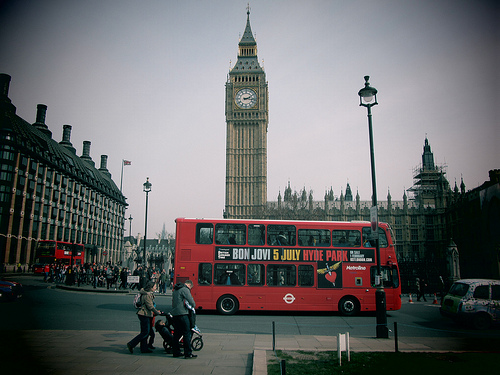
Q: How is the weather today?
A: It is partly cloudy.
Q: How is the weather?
A: It is partly cloudy.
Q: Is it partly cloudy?
A: Yes, it is partly cloudy.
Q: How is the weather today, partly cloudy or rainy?
A: It is partly cloudy.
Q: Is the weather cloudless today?
A: No, it is partly cloudy.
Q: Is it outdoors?
A: Yes, it is outdoors.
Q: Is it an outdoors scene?
A: Yes, it is outdoors.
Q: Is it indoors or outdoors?
A: It is outdoors.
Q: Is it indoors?
A: No, it is outdoors.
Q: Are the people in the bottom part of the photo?
A: Yes, the people are in the bottom of the image.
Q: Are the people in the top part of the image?
A: No, the people are in the bottom of the image.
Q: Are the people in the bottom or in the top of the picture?
A: The people are in the bottom of the image.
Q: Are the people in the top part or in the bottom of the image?
A: The people are in the bottom of the image.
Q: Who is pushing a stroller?
A: The people are pushing a stroller.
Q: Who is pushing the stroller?
A: The people are pushing a stroller.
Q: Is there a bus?
A: Yes, there is a bus.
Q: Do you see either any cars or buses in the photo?
A: Yes, there is a bus.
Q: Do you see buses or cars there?
A: Yes, there is a bus.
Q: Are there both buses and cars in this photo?
A: Yes, there are both a bus and a car.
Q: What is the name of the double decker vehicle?
A: The vehicle is a bus.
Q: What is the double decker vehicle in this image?
A: The vehicle is a bus.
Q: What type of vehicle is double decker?
A: The vehicle is a bus.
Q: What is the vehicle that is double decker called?
A: The vehicle is a bus.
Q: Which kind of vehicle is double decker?
A: The vehicle is a bus.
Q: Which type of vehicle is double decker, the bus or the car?
A: The bus is double decker.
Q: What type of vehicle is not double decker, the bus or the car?
A: The car is not double decker.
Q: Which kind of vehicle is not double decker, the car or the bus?
A: The car is not double decker.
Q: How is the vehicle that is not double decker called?
A: The vehicle is a car.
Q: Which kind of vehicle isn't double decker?
A: The vehicle is a car.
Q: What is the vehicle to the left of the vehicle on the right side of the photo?
A: The vehicle is a bus.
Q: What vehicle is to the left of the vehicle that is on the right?
A: The vehicle is a bus.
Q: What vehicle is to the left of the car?
A: The vehicle is a bus.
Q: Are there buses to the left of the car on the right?
A: Yes, there is a bus to the left of the car.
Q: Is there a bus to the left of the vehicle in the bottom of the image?
A: Yes, there is a bus to the left of the car.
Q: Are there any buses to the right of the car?
A: No, the bus is to the left of the car.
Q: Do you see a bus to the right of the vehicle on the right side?
A: No, the bus is to the left of the car.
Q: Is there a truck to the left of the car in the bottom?
A: No, there is a bus to the left of the car.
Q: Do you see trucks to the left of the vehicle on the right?
A: No, there is a bus to the left of the car.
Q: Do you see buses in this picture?
A: Yes, there is a bus.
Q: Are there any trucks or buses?
A: Yes, there is a bus.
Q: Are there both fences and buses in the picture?
A: No, there is a bus but no fences.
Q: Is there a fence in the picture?
A: No, there are no fences.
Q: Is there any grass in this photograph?
A: Yes, there is grass.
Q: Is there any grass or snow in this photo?
A: Yes, there is grass.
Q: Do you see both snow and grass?
A: No, there is grass but no snow.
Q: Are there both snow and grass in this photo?
A: No, there is grass but no snow.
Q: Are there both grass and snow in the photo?
A: No, there is grass but no snow.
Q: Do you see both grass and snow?
A: No, there is grass but no snow.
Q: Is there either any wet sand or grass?
A: Yes, there is wet grass.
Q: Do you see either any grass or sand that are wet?
A: Yes, the grass is wet.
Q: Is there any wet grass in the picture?
A: Yes, there is wet grass.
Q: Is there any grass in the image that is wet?
A: Yes, there is grass that is wet.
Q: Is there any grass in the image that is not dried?
A: Yes, there is wet grass.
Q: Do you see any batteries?
A: No, there are no batteries.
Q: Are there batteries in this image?
A: No, there are no batteries.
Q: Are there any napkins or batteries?
A: No, there are no batteries or napkins.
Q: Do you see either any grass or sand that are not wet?
A: No, there is grass but it is wet.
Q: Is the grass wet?
A: Yes, the grass is wet.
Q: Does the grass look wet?
A: Yes, the grass is wet.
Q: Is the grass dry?
A: No, the grass is wet.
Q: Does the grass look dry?
A: No, the grass is wet.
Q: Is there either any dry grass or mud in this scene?
A: No, there is grass but it is wet.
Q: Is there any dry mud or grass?
A: No, there is grass but it is wet.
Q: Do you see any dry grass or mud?
A: No, there is grass but it is wet.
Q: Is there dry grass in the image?
A: No, there is grass but it is wet.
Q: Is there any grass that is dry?
A: No, there is grass but it is wet.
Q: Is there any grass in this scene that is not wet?
A: No, there is grass but it is wet.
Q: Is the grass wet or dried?
A: The grass is wet.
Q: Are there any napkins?
A: No, there are no napkins.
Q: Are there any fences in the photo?
A: No, there are no fences.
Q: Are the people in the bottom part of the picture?
A: Yes, the people are in the bottom of the image.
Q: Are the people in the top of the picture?
A: No, the people are in the bottom of the image.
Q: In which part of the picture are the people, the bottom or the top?
A: The people are in the bottom of the image.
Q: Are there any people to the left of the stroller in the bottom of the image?
A: Yes, there are people to the left of the stroller.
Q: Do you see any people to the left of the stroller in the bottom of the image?
A: Yes, there are people to the left of the stroller.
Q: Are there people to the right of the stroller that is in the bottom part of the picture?
A: No, the people are to the left of the stroller.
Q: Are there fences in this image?
A: No, there are no fences.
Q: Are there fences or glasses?
A: No, there are no fences or glasses.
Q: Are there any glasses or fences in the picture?
A: No, there are no fences or glasses.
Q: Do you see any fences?
A: No, there are no fences.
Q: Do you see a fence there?
A: No, there are no fences.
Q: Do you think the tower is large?
A: Yes, the tower is large.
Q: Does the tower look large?
A: Yes, the tower is large.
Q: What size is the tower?
A: The tower is large.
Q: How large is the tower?
A: The tower is large.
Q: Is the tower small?
A: No, the tower is large.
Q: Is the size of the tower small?
A: No, the tower is large.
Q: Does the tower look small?
A: No, the tower is large.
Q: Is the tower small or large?
A: The tower is large.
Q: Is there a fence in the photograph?
A: No, there are no fences.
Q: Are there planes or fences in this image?
A: No, there are no fences or planes.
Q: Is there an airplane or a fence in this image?
A: No, there are no fences or airplanes.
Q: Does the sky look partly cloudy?
A: Yes, the sky is partly cloudy.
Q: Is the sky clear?
A: No, the sky is partly cloudy.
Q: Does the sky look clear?
A: No, the sky is partly cloudy.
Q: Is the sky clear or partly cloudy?
A: The sky is partly cloudy.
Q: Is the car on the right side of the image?
A: Yes, the car is on the right of the image.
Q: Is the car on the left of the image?
A: No, the car is on the right of the image.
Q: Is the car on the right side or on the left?
A: The car is on the right of the image.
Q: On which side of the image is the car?
A: The car is on the right of the image.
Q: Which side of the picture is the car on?
A: The car is on the right of the image.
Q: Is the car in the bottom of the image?
A: Yes, the car is in the bottom of the image.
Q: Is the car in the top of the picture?
A: No, the car is in the bottom of the image.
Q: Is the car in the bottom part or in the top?
A: The car is in the bottom of the image.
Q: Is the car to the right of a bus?
A: Yes, the car is to the right of a bus.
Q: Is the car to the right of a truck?
A: No, the car is to the right of a bus.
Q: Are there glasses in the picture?
A: No, there are no glasses.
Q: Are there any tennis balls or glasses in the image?
A: No, there are no glasses or tennis balls.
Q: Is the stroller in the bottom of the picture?
A: Yes, the stroller is in the bottom of the image.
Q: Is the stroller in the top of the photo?
A: No, the stroller is in the bottom of the image.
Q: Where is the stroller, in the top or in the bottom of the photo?
A: The stroller is in the bottom of the image.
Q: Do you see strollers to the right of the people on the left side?
A: Yes, there is a stroller to the right of the people.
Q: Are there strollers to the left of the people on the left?
A: No, the stroller is to the right of the people.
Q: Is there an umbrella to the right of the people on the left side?
A: No, there is a stroller to the right of the people.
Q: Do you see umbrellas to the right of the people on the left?
A: No, there is a stroller to the right of the people.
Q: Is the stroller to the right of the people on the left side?
A: Yes, the stroller is to the right of the people.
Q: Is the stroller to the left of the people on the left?
A: No, the stroller is to the right of the people.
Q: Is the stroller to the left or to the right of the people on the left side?
A: The stroller is to the right of the people.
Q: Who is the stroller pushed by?
A: The stroller is pushed by the people.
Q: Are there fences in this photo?
A: No, there are no fences.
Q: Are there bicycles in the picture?
A: No, there are no bicycles.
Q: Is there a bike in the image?
A: No, there are no bikes.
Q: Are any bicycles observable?
A: No, there are no bicycles.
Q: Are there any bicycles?
A: No, there are no bicycles.